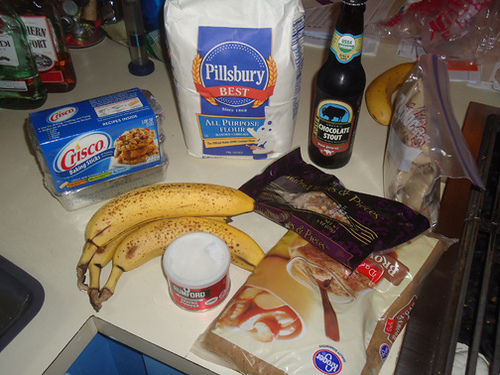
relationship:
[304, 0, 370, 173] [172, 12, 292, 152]
beer by flour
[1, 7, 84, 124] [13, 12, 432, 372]
bottles on table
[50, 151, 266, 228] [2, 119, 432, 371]
banana on table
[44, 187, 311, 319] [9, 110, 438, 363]
bananas are on counter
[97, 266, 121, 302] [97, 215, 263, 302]
stem on banana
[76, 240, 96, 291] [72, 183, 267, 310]
stem on banana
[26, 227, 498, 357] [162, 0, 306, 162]
flour in flour bag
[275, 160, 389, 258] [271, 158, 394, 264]
food in bag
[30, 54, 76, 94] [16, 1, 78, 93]
liquid in bottles